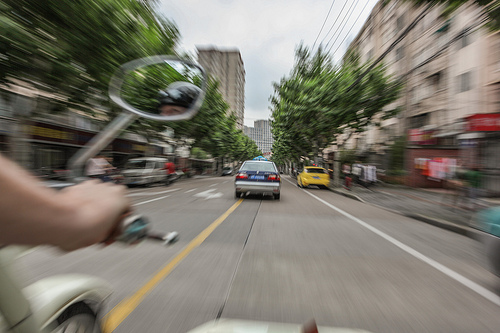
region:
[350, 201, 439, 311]
A white line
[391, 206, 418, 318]
A white line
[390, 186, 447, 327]
A white line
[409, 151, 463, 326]
A white line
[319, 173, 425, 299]
A white line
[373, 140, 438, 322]
A white line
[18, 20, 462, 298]
Picture looks odd because of motion blur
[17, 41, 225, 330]
Rider is on a scooter or motorcycle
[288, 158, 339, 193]
Parked yellow taxi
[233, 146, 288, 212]
Blue car in motion in front of the rider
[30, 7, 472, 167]
Riding down a city street with buildings and stores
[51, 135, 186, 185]
People walking across the street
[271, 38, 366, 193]
Row of green trees lining the street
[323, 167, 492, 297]
The parking lane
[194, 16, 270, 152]
Tall city buildings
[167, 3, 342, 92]
Grey cloudy sky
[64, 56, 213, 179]
a scooter silver mirror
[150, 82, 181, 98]
sunglasses reflection in the mirror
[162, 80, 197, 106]
a black helmet in the mirror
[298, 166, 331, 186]
a yellow car parked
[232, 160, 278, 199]
a blue and silver car driving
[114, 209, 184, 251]
a handle of a scooter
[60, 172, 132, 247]
the hand of a man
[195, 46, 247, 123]
a tall building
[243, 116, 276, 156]
a tall building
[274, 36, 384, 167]
a leafy green tree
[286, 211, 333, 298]
the street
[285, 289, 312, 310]
the street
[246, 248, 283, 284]
the street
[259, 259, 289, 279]
the street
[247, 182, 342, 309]
the street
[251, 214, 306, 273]
the street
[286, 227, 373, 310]
the street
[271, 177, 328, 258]
the street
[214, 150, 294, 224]
the street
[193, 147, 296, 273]
the street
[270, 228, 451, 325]
the street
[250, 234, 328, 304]
the street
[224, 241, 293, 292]
the street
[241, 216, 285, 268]
the street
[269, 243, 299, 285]
the street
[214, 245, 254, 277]
the street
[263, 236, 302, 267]
the street